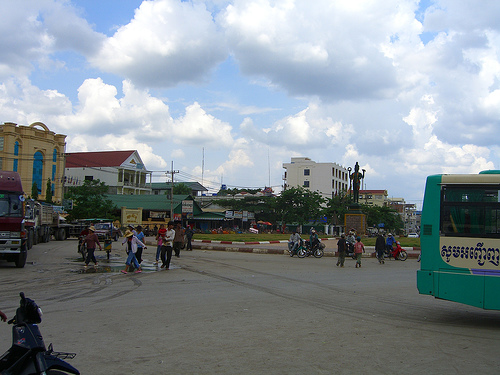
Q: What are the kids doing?
A: Playing in a puddle.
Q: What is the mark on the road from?
A: Wet tires.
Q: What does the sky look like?
A: Cloudy.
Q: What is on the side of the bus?
A: Windows.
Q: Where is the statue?
A: Middle of town.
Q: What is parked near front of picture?
A: Moped.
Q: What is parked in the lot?
A: Bus.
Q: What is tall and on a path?
A: A statue.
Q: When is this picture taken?
A: Daytime.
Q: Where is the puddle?
A: On the road.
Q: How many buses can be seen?
A: 1.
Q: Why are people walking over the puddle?
A: To not get wet.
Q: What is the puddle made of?
A: Water.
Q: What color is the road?
A: Gray.